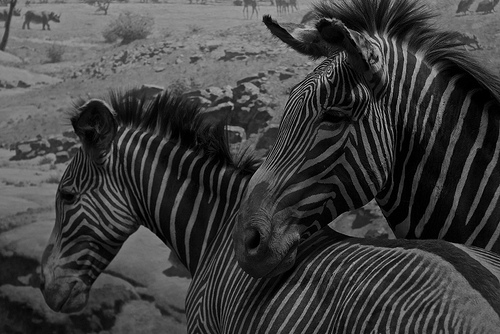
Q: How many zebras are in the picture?
A: Two.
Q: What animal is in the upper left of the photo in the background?
A: A rhinoceros.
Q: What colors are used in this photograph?
A: Black and White.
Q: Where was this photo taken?
A: In the desert.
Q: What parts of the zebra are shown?
A: The head and neck and back.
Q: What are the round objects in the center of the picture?
A: Rocks.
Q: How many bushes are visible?
A: One.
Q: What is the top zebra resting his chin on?
A: The back of another zebra.